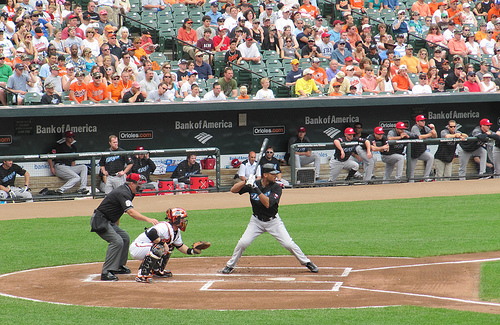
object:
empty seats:
[156, 15, 175, 30]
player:
[0, 157, 33, 202]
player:
[128, 146, 155, 190]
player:
[170, 151, 201, 183]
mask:
[125, 173, 148, 195]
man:
[258, 147, 290, 191]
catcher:
[124, 205, 208, 286]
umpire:
[87, 171, 161, 281]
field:
[2, 174, 499, 323]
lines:
[136, 241, 356, 308]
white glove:
[245, 172, 256, 190]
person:
[69, 72, 90, 104]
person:
[85, 72, 108, 99]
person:
[107, 74, 124, 103]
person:
[119, 69, 134, 102]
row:
[69, 66, 139, 106]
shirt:
[69, 80, 89, 100]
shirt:
[89, 80, 106, 99]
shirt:
[120, 80, 133, 95]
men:
[68, 71, 90, 103]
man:
[330, 124, 372, 186]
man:
[362, 124, 391, 184]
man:
[382, 122, 412, 185]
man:
[409, 113, 438, 184]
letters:
[173, 119, 232, 131]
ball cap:
[374, 126, 385, 134]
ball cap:
[394, 121, 406, 129]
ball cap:
[412, 110, 426, 123]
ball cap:
[479, 118, 493, 125]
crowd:
[0, 0, 499, 105]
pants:
[225, 215, 319, 274]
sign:
[172, 118, 235, 129]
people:
[295, 68, 324, 100]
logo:
[173, 118, 234, 130]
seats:
[139, 11, 161, 20]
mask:
[162, 207, 191, 232]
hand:
[147, 217, 159, 227]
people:
[257, 77, 275, 101]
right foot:
[222, 265, 235, 274]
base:
[263, 274, 298, 282]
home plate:
[84, 258, 363, 296]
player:
[97, 134, 134, 210]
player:
[126, 142, 161, 189]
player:
[167, 152, 213, 188]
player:
[286, 122, 323, 187]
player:
[430, 120, 470, 182]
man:
[87, 173, 150, 283]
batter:
[218, 162, 323, 274]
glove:
[191, 240, 214, 255]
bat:
[251, 137, 267, 174]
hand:
[244, 176, 255, 185]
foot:
[222, 266, 235, 273]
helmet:
[260, 165, 281, 175]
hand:
[187, 242, 205, 256]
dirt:
[188, 261, 357, 295]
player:
[467, 116, 500, 182]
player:
[45, 127, 84, 197]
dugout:
[5, 102, 500, 196]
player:
[48, 129, 92, 196]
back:
[134, 220, 168, 238]